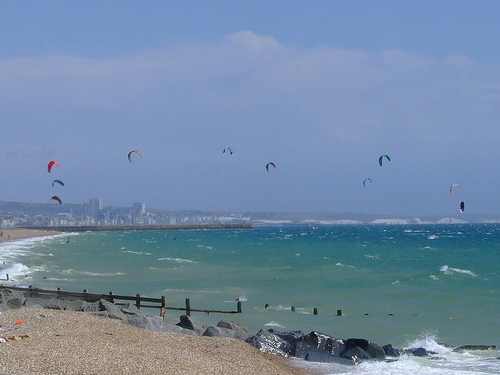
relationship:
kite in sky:
[48, 176, 69, 191] [2, 0, 482, 215]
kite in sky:
[127, 148, 138, 163] [2, 0, 482, 215]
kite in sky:
[378, 155, 392, 167] [2, 0, 482, 215]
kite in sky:
[263, 160, 280, 173] [2, 0, 482, 215]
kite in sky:
[457, 199, 466, 215] [2, 0, 482, 215]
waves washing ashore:
[1, 229, 81, 285] [1, 226, 61, 245]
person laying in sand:
[2, 325, 32, 345] [1, 305, 306, 373]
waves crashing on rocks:
[348, 329, 461, 373] [244, 324, 433, 368]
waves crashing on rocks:
[354, 327, 457, 373] [249, 314, 438, 369]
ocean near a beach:
[0, 220, 500, 375] [2, 225, 307, 373]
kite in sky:
[45, 159, 62, 175] [2, 0, 482, 215]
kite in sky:
[49, 193, 64, 207] [2, 0, 482, 215]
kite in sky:
[50, 179, 63, 190] [2, 0, 482, 215]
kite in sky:
[124, 148, 144, 166] [2, 0, 482, 215]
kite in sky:
[218, 143, 236, 156] [2, 0, 482, 215]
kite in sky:
[265, 161, 275, 172] [2, 0, 482, 215]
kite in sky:
[359, 173, 376, 188] [2, 0, 482, 215]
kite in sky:
[374, 150, 393, 166] [2, 0, 482, 215]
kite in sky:
[446, 176, 464, 195] [2, 0, 482, 215]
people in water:
[63, 228, 73, 250] [3, 222, 483, 370]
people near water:
[0, 224, 15, 244] [3, 222, 483, 370]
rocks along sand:
[96, 295, 437, 361] [1, 305, 305, 374]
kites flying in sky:
[45, 142, 466, 214] [2, 0, 482, 215]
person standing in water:
[155, 299, 168, 322] [3, 222, 483, 370]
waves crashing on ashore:
[0, 229, 80, 287] [0, 226, 61, 243]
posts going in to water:
[3, 277, 373, 318] [3, 222, 483, 370]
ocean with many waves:
[0, 220, 485, 372] [0, 225, 89, 290]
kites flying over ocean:
[45, 142, 466, 214] [0, 220, 485, 372]